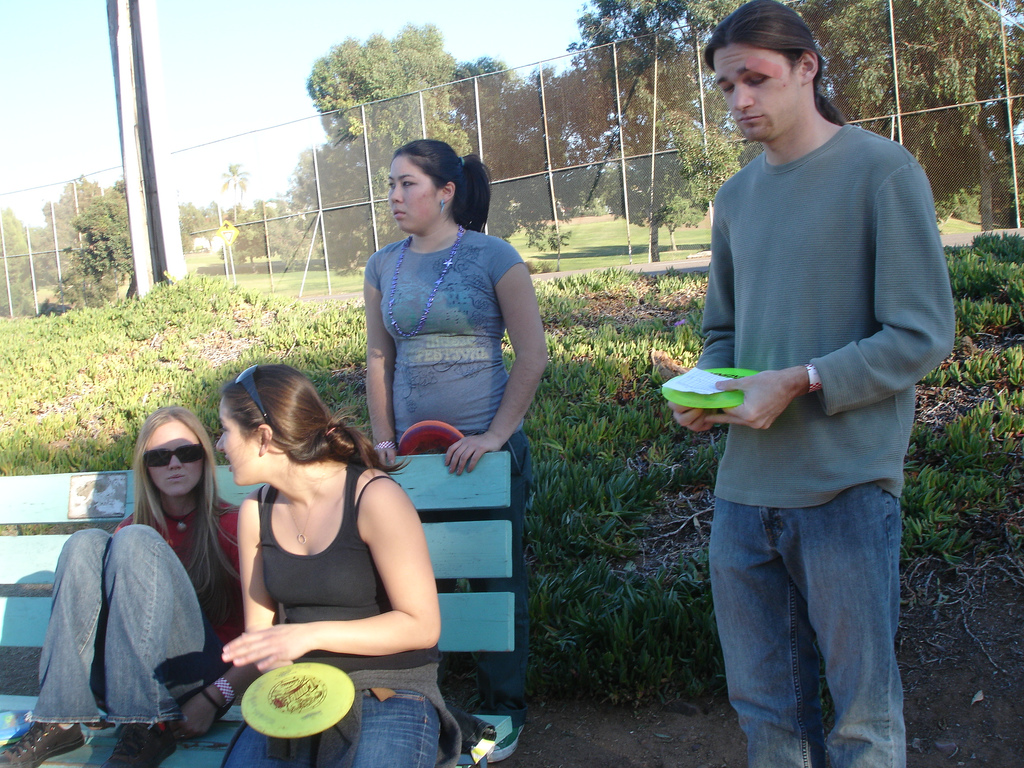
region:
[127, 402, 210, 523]
the head of the girl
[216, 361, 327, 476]
the head of the girl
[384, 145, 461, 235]
the head of the girl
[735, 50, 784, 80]
the band aid on the face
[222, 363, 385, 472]
the brown hair on the head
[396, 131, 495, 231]
the brown hair on the head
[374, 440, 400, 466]
the hand of the girl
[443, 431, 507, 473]
the hand of the girl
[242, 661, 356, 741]
a girl is holding a frisbee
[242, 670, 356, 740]
the woman has a yellow frisbee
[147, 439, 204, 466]
a woman is wearing black glasses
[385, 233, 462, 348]
a woman wears a necklace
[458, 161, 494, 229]
woman wears a ponytail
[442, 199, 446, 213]
woman wears earrings in here ears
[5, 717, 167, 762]
a woman wears black shoes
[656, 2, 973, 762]
man holding green frisbee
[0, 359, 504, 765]
women sitting on park bench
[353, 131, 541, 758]
woman standing with red frisbee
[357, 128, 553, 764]
woman wearing purple neckace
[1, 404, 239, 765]
woman sitting with feet on bench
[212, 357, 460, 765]
woman holding yellow frisbee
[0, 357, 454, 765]
two women with sunglasses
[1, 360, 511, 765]
women sitting on green bench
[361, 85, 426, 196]
fence section is metal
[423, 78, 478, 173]
fence section is metal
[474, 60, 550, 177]
fence section is metal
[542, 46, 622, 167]
fence section is metal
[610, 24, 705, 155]
fence section is metal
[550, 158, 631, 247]
fence section is metal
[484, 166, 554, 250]
fence section is metal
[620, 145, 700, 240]
fence section is metal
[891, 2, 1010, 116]
fence section is metal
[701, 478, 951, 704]
legs of the person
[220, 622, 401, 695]
hand of the girl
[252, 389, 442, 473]
hairs of the girl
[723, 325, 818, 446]
hand of the boy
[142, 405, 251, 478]
glasses of the girl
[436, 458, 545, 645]
a view of bench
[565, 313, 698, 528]
a view of grass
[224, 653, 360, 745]
girl holding a frisbee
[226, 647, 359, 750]
girls frisbee is yellow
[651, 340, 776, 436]
man's frisbee is green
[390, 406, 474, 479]
woman's frisbee is red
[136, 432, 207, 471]
girl wearing pair of sunglasses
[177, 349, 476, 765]
girl sitting on bench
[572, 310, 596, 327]
A green leaf on a plant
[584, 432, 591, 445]
A green leaf on a plant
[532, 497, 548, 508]
A green leaf on a plant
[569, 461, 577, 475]
A green leaf on a plant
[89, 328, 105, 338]
A green leaf on a plant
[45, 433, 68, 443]
A green leaf on a plant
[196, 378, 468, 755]
A person is sitting down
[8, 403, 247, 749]
A person is sitting down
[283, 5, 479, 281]
A tree in a field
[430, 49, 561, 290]
A tree in a field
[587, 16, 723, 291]
A tree in a field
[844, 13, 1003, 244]
A tree in a field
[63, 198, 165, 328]
A tree in a field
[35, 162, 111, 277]
A tree in a field